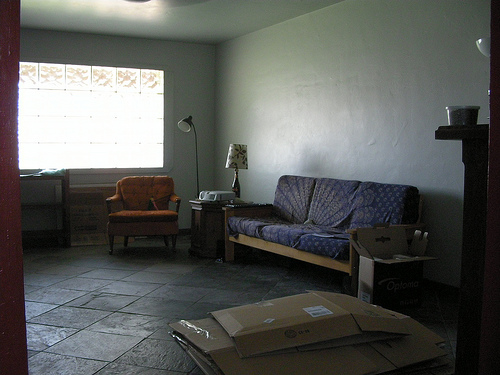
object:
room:
[0, 0, 500, 375]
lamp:
[224, 143, 248, 203]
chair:
[106, 175, 182, 255]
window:
[18, 61, 166, 170]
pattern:
[227, 144, 248, 169]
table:
[188, 198, 274, 258]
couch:
[222, 175, 423, 297]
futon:
[226, 174, 423, 259]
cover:
[227, 175, 420, 259]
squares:
[19, 62, 164, 170]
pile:
[171, 290, 453, 375]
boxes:
[170, 289, 457, 375]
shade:
[297, 152, 328, 175]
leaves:
[237, 154, 240, 159]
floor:
[18, 247, 469, 371]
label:
[302, 305, 333, 318]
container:
[445, 105, 480, 125]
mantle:
[433, 124, 499, 140]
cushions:
[229, 216, 350, 262]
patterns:
[252, 176, 375, 231]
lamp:
[176, 116, 200, 198]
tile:
[117, 297, 195, 319]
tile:
[84, 311, 174, 338]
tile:
[115, 336, 197, 374]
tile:
[143, 284, 215, 303]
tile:
[94, 280, 165, 296]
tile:
[24, 285, 89, 304]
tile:
[37, 264, 97, 275]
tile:
[43, 330, 145, 362]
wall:
[11, 40, 226, 249]